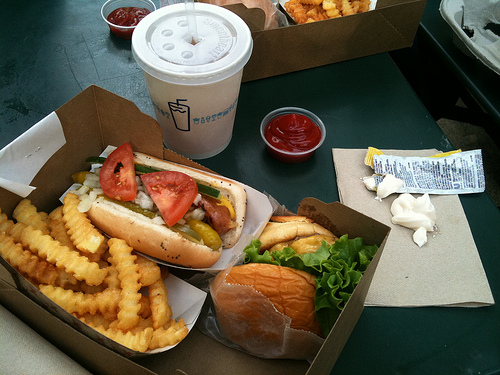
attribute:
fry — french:
[107, 236, 142, 329]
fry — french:
[68, 315, 151, 353]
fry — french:
[61, 193, 104, 255]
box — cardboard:
[241, 1, 424, 82]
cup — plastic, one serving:
[259, 107, 326, 162]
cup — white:
[146, 67, 246, 160]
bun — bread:
[212, 263, 321, 347]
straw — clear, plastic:
[184, 0, 197, 44]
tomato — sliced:
[98, 142, 139, 204]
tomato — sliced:
[139, 171, 197, 226]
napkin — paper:
[332, 147, 495, 308]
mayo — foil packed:
[390, 191, 435, 248]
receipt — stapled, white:
[0, 110, 68, 198]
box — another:
[0, 84, 392, 375]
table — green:
[194, 52, 447, 215]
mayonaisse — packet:
[365, 146, 487, 194]